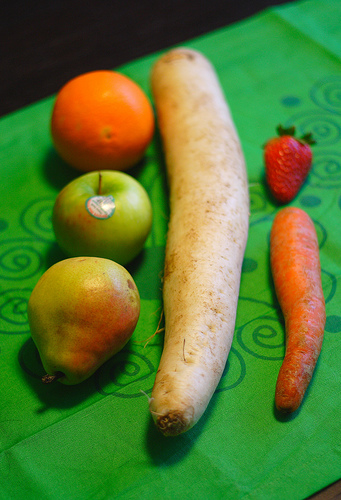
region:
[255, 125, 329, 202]
A strawberry on a cloth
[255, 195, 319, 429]
A carrot on a cloth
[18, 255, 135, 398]
A pair on a cloth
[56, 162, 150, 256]
A apple on a cloth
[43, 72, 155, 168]
A orange on a cloth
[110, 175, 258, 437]
A vegatable on a cloth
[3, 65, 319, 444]
Furits and vegetables on a cloth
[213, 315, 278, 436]
The cloth has circle designs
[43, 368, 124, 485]
The cloth is green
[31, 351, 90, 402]
The top of a pear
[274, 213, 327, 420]
orange carrot on green napkin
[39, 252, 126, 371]
pear on green napkin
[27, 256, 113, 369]
pear is green and red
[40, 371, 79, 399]
stem of red and green pear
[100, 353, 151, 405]
circular design on green napkin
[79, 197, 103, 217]
label on round apple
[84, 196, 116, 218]
label is white and round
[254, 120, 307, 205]
red strawberry above carrot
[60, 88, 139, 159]
orange orange above apple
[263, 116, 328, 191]
red strawberry on green napkin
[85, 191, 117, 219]
sticker on the apple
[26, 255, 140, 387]
red and green pear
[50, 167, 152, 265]
green and red medium apple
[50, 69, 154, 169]
bright orange, orange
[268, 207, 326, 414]
crooked orange carrot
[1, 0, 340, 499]
light green cloth with dark green swirl decoration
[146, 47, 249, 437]
long white root vegetable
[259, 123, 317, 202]
ripe red strawberry with a stem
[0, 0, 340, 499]
dark wood table top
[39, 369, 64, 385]
pears dark brown stem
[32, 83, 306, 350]
Fruit on a green cloth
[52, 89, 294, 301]
An orange, pear, carrot, strawberry, green apple and parsnip on a cloth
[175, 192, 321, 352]
Vegetables on the cloth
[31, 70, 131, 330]
Fruit on the cloth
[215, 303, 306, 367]
Green swirls on a cloth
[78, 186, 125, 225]
Sticker on the apple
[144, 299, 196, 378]
Tiny roots on the parsnip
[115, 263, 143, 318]
A bruise on the pear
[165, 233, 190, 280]
Dirt on the parsnip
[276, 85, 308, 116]
Green dots as part of the pattern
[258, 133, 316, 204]
The strawberry is red.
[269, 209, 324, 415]
The carrot is orange.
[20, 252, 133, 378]
The pear is green.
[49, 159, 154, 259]
The apple is green.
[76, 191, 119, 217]
The apple has a sticker on it.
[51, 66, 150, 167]
The orange is orange.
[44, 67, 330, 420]
The fruit is on the table.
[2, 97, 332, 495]
The fruit is on a table cloth.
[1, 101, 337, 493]
The table cloth is green.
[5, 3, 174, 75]
The table is brown.